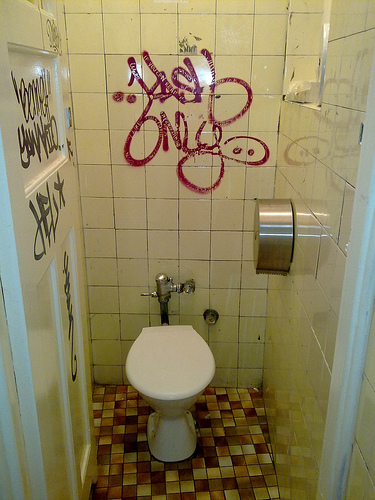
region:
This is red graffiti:
[114, 54, 250, 276]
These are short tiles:
[120, 455, 152, 494]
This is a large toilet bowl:
[117, 326, 261, 493]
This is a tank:
[130, 290, 206, 317]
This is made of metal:
[130, 285, 157, 315]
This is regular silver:
[143, 270, 196, 334]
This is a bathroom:
[38, 282, 263, 465]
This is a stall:
[72, 230, 294, 493]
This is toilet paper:
[229, 226, 302, 271]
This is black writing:
[34, 218, 45, 231]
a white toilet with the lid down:
[122, 274, 218, 463]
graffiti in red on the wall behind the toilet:
[119, 49, 272, 194]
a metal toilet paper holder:
[253, 197, 293, 274]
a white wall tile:
[113, 197, 147, 229]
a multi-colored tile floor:
[92, 385, 278, 497]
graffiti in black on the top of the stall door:
[9, 70, 64, 168]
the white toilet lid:
[123, 325, 216, 398]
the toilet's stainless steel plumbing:
[140, 275, 196, 324]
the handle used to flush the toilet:
[139, 286, 157, 298]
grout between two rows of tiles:
[80, 160, 276, 168]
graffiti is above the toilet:
[112, 42, 267, 192]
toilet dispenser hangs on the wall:
[243, 192, 291, 273]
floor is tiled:
[86, 376, 281, 496]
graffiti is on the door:
[4, 54, 58, 163]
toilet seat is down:
[123, 321, 220, 405]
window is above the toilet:
[287, 1, 335, 107]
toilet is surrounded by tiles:
[85, 322, 278, 495]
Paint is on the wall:
[107, 45, 273, 204]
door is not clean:
[5, 55, 80, 382]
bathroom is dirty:
[2, 1, 373, 498]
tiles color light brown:
[230, 465, 252, 488]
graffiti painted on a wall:
[72, 7, 272, 221]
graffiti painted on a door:
[12, 49, 95, 395]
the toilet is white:
[117, 315, 217, 466]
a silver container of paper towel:
[242, 188, 299, 282]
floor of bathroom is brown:
[91, 383, 274, 495]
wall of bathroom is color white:
[77, 5, 358, 269]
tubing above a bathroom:
[128, 265, 205, 333]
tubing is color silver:
[131, 266, 197, 333]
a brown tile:
[189, 477, 208, 495]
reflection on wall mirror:
[282, 1, 331, 110]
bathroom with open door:
[2, 19, 373, 499]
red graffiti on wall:
[114, 47, 270, 191]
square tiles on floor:
[62, 1, 283, 385]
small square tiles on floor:
[92, 385, 276, 497]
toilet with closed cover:
[125, 324, 213, 461]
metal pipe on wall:
[142, 272, 195, 325]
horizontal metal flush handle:
[138, 290, 158, 298]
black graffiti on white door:
[2, 1, 96, 498]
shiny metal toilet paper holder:
[253, 198, 293, 273]